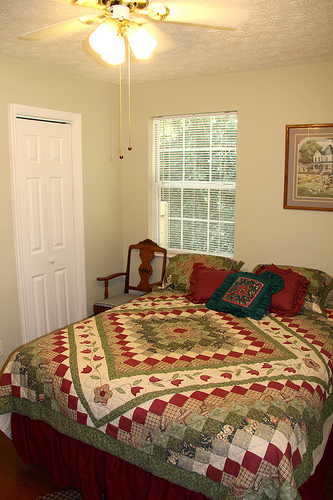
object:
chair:
[91, 237, 168, 318]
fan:
[18, 0, 248, 71]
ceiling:
[0, 0, 332, 83]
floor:
[0, 422, 90, 499]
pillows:
[205, 265, 286, 327]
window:
[149, 105, 239, 265]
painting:
[282, 122, 333, 216]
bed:
[0, 251, 333, 500]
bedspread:
[0, 250, 333, 499]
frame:
[282, 120, 331, 214]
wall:
[119, 62, 333, 295]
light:
[127, 28, 159, 63]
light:
[100, 34, 127, 65]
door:
[10, 109, 85, 341]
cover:
[205, 270, 285, 321]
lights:
[88, 18, 115, 60]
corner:
[109, 81, 136, 303]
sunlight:
[150, 108, 238, 258]